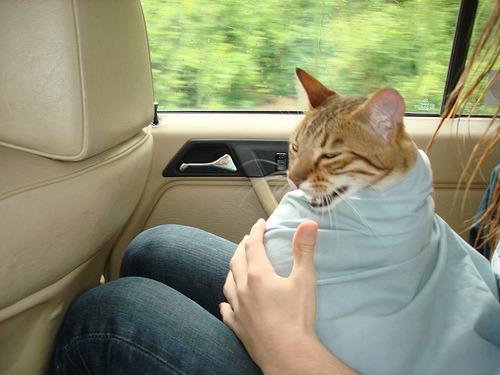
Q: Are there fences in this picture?
A: No, there are no fences.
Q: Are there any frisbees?
A: No, there are no frisbees.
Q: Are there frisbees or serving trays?
A: No, there are no frisbees or serving trays.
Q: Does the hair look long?
A: Yes, the hair is long.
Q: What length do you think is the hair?
A: The hair is long.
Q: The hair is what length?
A: The hair is long.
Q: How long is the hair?
A: The hair is long.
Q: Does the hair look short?
A: No, the hair is long.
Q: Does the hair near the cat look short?
A: No, the hair is long.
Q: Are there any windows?
A: Yes, there is a window.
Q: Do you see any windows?
A: Yes, there is a window.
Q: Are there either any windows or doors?
A: Yes, there is a window.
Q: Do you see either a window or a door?
A: Yes, there is a window.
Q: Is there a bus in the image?
A: No, there are no buses.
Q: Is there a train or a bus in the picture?
A: No, there are no buses or trains.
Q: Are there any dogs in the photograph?
A: No, there are no dogs.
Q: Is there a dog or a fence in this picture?
A: No, there are no dogs or fences.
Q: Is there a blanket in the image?
A: Yes, there is a blanket.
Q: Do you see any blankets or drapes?
A: Yes, there is a blanket.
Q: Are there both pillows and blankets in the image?
A: No, there is a blanket but no pillows.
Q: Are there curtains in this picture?
A: No, there are no curtains.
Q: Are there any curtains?
A: No, there are no curtains.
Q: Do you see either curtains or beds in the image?
A: No, there are no curtains or beds.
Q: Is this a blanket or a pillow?
A: This is a blanket.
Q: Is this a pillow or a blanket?
A: This is a blanket.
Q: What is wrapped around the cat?
A: The blanket is wrapped around the cat.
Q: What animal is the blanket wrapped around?
A: The blanket is wrapped around the cat.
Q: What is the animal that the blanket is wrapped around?
A: The animal is a cat.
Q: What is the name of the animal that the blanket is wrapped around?
A: The animal is a cat.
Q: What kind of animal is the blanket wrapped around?
A: The blanket is wrapped around the cat.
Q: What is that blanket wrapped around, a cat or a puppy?
A: The blanket is wrapped around a cat.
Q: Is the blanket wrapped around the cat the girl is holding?
A: Yes, the blanket is wrapped around the cat.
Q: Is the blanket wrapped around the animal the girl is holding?
A: Yes, the blanket is wrapped around the cat.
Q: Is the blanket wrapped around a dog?
A: No, the blanket is wrapped around the cat.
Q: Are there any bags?
A: No, there are no bags.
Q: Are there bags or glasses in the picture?
A: No, there are no bags or glasses.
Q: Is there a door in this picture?
A: Yes, there is a door.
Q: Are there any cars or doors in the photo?
A: Yes, there is a door.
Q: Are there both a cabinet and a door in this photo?
A: No, there is a door but no cabinets.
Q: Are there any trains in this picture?
A: No, there are no trains.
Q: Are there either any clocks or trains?
A: No, there are no trains or clocks.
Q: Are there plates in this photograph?
A: No, there are no plates.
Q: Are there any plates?
A: No, there are no plates.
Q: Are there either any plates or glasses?
A: No, there are no plates or glasses.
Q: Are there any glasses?
A: No, there are no glasses.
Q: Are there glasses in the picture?
A: No, there are no glasses.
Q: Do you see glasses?
A: No, there are no glasses.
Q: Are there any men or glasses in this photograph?
A: No, there are no glasses or men.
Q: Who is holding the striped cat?
A: The girl is holding the cat.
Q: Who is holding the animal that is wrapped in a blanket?
A: The girl is holding the cat.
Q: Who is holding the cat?
A: The girl is holding the cat.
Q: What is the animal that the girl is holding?
A: The animal is a cat.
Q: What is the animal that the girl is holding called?
A: The animal is a cat.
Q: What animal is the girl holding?
A: The girl is holding the cat.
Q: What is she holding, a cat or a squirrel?
A: The girl is holding a cat.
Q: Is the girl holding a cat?
A: Yes, the girl is holding a cat.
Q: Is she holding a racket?
A: No, the girl is holding a cat.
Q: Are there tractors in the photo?
A: No, there are no tractors.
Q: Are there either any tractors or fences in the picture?
A: No, there are no tractors or fences.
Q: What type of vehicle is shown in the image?
A: The vehicle is a car.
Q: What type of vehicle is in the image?
A: The vehicle is a car.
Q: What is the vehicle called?
A: The vehicle is a car.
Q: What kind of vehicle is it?
A: The vehicle is a car.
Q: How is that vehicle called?
A: This is a car.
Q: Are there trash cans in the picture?
A: No, there are no trash cans.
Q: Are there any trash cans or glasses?
A: No, there are no trash cans or glasses.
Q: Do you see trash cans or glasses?
A: No, there are no trash cans or glasses.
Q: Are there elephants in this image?
A: No, there are no elephants.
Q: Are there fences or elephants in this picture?
A: No, there are no elephants or fences.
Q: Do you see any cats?
A: Yes, there is a cat.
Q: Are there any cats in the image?
A: Yes, there is a cat.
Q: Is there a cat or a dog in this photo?
A: Yes, there is a cat.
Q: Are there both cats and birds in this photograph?
A: No, there is a cat but no birds.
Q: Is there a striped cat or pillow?
A: Yes, there is a striped cat.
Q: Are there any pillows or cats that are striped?
A: Yes, the cat is striped.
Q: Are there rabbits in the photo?
A: No, there are no rabbits.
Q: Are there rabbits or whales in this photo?
A: No, there are no rabbits or whales.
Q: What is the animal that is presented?
A: The animal is a cat.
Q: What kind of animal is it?
A: The animal is a cat.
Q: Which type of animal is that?
A: This is a cat.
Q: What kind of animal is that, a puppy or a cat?
A: This is a cat.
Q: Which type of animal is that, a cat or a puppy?
A: This is a cat.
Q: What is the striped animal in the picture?
A: The animal is a cat.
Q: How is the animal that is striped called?
A: The animal is a cat.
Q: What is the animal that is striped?
A: The animal is a cat.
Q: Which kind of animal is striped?
A: The animal is a cat.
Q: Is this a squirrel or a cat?
A: This is a cat.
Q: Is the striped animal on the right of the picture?
A: Yes, the cat is on the right of the image.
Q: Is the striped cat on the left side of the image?
A: No, the cat is on the right of the image.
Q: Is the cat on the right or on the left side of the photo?
A: The cat is on the right of the image.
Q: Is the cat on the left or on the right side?
A: The cat is on the right of the image.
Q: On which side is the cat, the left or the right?
A: The cat is on the right of the image.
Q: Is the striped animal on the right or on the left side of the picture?
A: The cat is on the right of the image.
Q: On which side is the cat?
A: The cat is on the right of the image.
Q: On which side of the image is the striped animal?
A: The cat is on the right of the image.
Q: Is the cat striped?
A: Yes, the cat is striped.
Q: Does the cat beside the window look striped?
A: Yes, the cat is striped.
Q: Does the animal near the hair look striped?
A: Yes, the cat is striped.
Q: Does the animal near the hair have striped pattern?
A: Yes, the cat is striped.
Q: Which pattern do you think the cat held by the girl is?
A: The cat is striped.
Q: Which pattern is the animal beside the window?
A: The cat is striped.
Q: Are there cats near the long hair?
A: Yes, there is a cat near the hair.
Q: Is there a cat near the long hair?
A: Yes, there is a cat near the hair.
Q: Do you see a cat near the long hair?
A: Yes, there is a cat near the hair.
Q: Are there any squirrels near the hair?
A: No, there is a cat near the hair.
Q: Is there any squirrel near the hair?
A: No, there is a cat near the hair.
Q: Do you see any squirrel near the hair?
A: No, there is a cat near the hair.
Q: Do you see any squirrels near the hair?
A: No, there is a cat near the hair.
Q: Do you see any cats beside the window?
A: Yes, there is a cat beside the window.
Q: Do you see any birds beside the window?
A: No, there is a cat beside the window.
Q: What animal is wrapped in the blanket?
A: The cat is wrapped in the blanket.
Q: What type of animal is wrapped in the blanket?
A: The animal is a cat.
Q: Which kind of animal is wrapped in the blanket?
A: The animal is a cat.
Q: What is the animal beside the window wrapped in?
A: The cat is wrapped in a blanket.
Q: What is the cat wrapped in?
A: The cat is wrapped in a blanket.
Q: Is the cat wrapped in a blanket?
A: Yes, the cat is wrapped in a blanket.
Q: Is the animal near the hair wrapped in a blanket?
A: Yes, the cat is wrapped in a blanket.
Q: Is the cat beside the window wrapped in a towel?
A: No, the cat is wrapped in a blanket.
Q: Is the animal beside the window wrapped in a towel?
A: No, the cat is wrapped in a blanket.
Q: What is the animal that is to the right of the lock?
A: The animal is a cat.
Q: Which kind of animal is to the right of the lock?
A: The animal is a cat.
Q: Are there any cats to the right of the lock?
A: Yes, there is a cat to the right of the lock.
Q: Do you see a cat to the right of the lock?
A: Yes, there is a cat to the right of the lock.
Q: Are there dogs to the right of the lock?
A: No, there is a cat to the right of the lock.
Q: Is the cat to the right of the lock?
A: Yes, the cat is to the right of the lock.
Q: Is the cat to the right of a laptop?
A: No, the cat is to the right of the lock.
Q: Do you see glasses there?
A: No, there are no glasses.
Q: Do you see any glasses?
A: No, there are no glasses.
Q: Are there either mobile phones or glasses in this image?
A: No, there are no glasses or mobile phones.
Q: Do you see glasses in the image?
A: No, there are no glasses.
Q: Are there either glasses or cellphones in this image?
A: No, there are no glasses or cellphones.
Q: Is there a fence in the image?
A: No, there are no fences.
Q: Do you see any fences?
A: No, there are no fences.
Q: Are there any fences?
A: No, there are no fences.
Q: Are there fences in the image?
A: No, there are no fences.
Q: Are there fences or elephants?
A: No, there are no fences or elephants.